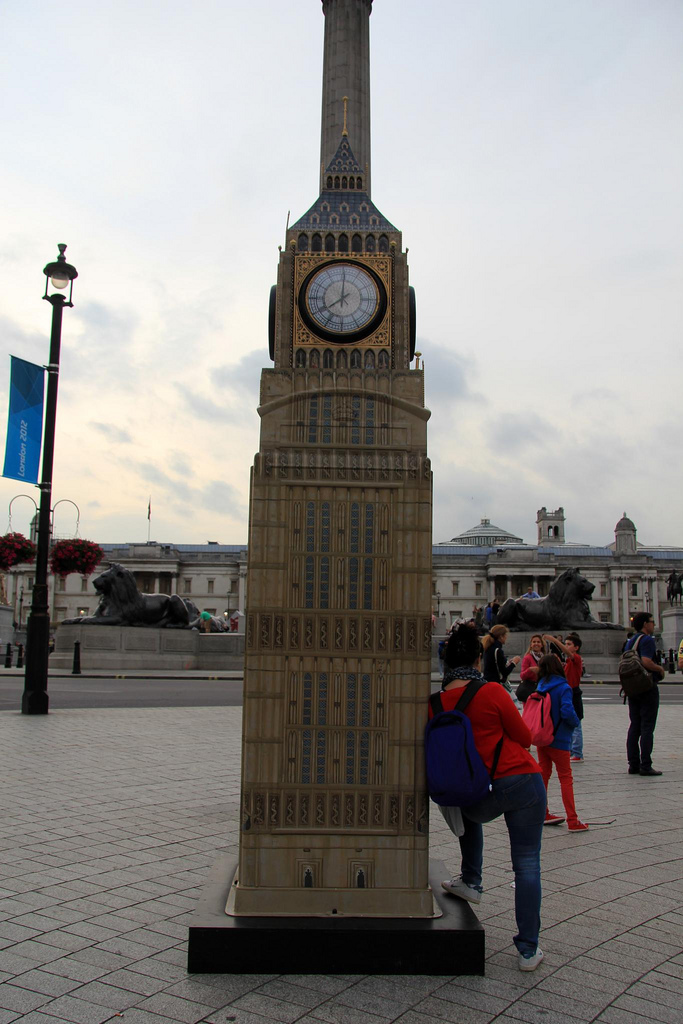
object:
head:
[437, 622, 485, 676]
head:
[481, 624, 508, 652]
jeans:
[458, 770, 548, 959]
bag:
[425, 677, 504, 806]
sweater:
[429, 681, 542, 780]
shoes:
[441, 873, 544, 972]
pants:
[537, 747, 578, 826]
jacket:
[534, 674, 579, 751]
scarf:
[442, 666, 488, 690]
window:
[55, 573, 66, 593]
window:
[82, 580, 88, 593]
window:
[295, 348, 306, 369]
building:
[221, 0, 442, 919]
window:
[159, 574, 172, 595]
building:
[117, 540, 246, 628]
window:
[208, 581, 214, 594]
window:
[183, 577, 191, 594]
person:
[422, 624, 554, 972]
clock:
[297, 257, 387, 344]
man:
[619, 611, 666, 775]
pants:
[626, 685, 659, 764]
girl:
[521, 633, 588, 831]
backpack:
[521, 681, 568, 749]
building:
[0, 544, 177, 668]